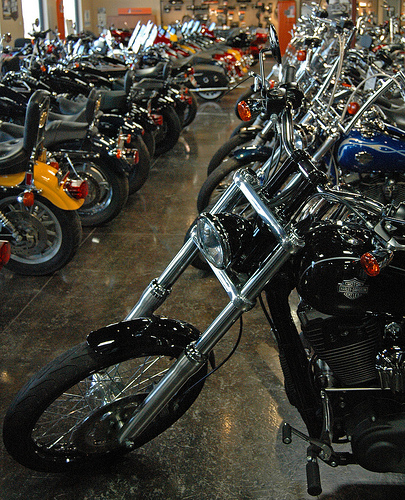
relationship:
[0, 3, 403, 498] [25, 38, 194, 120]
group of harleys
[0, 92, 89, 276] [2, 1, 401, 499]
motorcycle in shop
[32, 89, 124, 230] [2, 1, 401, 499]
motorcycle in shop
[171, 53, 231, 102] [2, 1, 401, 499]
motorcycle in shop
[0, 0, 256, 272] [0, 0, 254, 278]
motorcycles parked in a row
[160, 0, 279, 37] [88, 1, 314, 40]
items on wall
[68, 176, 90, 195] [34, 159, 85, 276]
light on back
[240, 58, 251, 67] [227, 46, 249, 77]
light on back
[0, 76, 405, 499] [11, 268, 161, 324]
floor has tile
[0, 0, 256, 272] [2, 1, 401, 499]
motorcycles lined up in store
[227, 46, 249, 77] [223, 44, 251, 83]
back of a motorcycle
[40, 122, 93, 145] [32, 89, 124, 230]
seat on motorcycle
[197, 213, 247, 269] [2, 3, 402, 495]
headlight of motorcycle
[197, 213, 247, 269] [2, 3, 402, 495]
headlight of a motorcycle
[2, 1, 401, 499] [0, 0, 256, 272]
shop for motorcycles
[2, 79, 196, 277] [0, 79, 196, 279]
tires are in a row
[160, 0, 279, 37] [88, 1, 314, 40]
items hanging on wall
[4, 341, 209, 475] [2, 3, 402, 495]
tire of a motorcycle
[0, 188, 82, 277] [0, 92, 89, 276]
tire on a motorcycle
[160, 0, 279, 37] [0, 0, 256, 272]
items for motorcycles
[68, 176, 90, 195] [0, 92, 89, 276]
light of a motorcycle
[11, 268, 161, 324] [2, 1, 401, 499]
tile of shop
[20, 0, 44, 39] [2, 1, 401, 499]
window to shop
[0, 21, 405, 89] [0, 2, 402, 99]
bikes in background